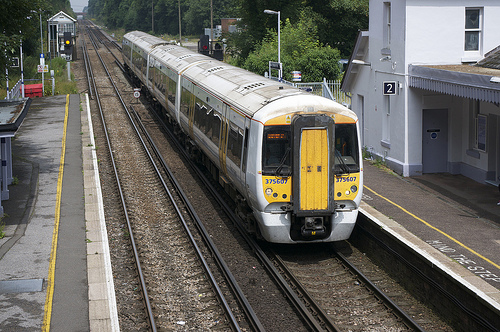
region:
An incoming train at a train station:
[112, 21, 370, 252]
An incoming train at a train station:
[117, 25, 362, 255]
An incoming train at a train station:
[117, 27, 363, 248]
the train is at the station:
[119, 27, 370, 247]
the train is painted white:
[121, 21, 364, 251]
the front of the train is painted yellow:
[261, 108, 358, 220]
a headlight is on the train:
[343, 187, 351, 197]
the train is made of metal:
[122, 23, 373, 250]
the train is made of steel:
[122, 25, 365, 254]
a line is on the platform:
[42, 89, 75, 327]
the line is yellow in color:
[43, 91, 75, 326]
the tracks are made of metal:
[76, 25, 412, 330]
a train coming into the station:
[42, 7, 481, 319]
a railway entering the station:
[30, 3, 490, 304]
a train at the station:
[32, 8, 487, 295]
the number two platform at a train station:
[357, 0, 487, 323]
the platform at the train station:
[1, 3, 88, 330]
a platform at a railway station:
[2, 5, 120, 299]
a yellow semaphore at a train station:
[36, 11, 174, 169]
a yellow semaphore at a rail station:
[29, 6, 108, 121]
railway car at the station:
[170, 49, 485, 264]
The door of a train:
[303, 131, 323, 208]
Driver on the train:
[337, 138, 347, 148]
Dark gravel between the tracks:
[258, 295, 281, 315]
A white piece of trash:
[176, 320, 183, 323]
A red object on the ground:
[27, 85, 36, 90]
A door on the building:
[425, 115, 445, 168]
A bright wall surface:
[412, 15, 452, 54]